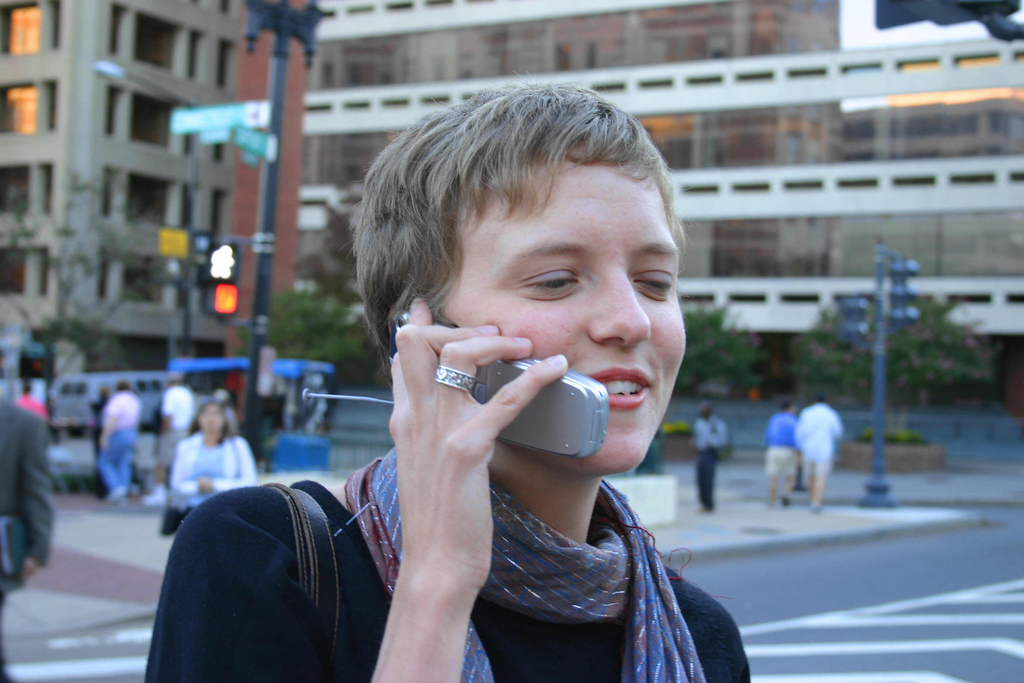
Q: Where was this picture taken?
A: On a city street.